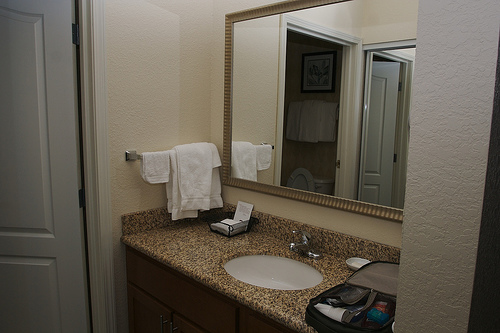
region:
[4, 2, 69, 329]
opened white door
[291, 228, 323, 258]
Steel tap of basin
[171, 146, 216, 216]
White towel on stand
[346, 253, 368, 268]
White soap stand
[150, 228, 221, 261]
Dotted brown and white mosaic slab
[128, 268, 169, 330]
Wooden modular shelves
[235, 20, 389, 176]
Mirror fixed to wall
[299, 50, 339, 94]
painting hanging on wall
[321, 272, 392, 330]
Opened bathroom kit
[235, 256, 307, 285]
White wash basin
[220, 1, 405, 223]
A large framed mirror on a wall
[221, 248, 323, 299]
A white ceramic sink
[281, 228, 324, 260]
The metal faucet for the sink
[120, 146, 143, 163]
The mounted part of a towel rack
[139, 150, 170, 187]
A white face cloth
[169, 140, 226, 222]
Towels hung on a rack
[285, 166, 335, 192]
The top of a toilet being reflected in the mirror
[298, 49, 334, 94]
A framed picture in the mirror's reflection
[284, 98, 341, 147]
A rack of towels in the mirror's reflection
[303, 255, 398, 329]
A toiletry bag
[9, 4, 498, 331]
This is a bathroom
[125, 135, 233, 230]
White towel on rack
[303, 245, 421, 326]
Toiletries bag on counter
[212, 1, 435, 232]
Large mirror above sink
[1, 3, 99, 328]
This is a door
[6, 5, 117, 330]
This door is open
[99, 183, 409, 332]
Marble sink counter top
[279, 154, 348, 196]
Reflection of toilet in mirror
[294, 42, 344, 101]
Reflection of picture in mirror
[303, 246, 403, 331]
Black toiletries holder bag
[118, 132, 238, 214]
towels on the rack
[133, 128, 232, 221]
white towels in photo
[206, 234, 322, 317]
white sink in photo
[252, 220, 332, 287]
faucet above the sink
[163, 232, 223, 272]
counter top in photo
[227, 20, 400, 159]
mirror in the photo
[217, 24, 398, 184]
mirror above the sink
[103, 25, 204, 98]
wall next to towels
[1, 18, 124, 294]
door on the left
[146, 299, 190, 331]
cabinet under the sink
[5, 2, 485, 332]
Bathroom in a building.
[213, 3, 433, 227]
Mirror on bathroom wall.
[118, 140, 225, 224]
White towels hanging on a rack.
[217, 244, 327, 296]
An oval bathroom sink.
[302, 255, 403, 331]
A black toiletry bag.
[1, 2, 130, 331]
The white door of a bathroom.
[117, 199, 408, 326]
Bathroom counter top.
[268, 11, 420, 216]
Door reflection in a mirror.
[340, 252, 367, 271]
A soap dish on a counter.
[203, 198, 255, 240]
A basket of soap on a counter.